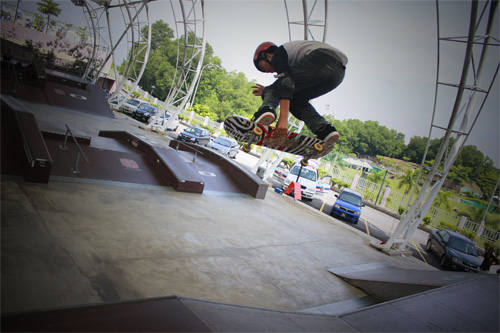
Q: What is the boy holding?
A: Skateboard.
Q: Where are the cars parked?
A: In parking lot.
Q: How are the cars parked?
A: Facing skatepark.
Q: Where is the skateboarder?
A: In the air.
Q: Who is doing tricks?
A: The skateboarder.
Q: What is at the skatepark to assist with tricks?
A: Skate ramps.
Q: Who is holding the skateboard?
A: The boy.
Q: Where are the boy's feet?
A: On skateboard.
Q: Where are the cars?
A: In the distance.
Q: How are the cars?
A: Parked.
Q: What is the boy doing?
A: Skateboarding.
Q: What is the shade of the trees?
A: Green.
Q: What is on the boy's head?
A: Helmet.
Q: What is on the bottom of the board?
A: Wheels.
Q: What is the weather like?
A: Sunny.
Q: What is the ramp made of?
A: Concrete..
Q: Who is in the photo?
A: A boy.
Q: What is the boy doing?
A: Skateboarding.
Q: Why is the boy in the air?
A: Doing a skateboard trick.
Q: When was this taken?
A: During the day.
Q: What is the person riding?
A: A skateboard.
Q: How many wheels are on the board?
A: Four.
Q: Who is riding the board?
A: A skater.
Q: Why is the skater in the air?
A: He went off a jump.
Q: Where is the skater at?
A: A skatepark.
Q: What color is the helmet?
A: Red.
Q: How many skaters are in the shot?
A: One.